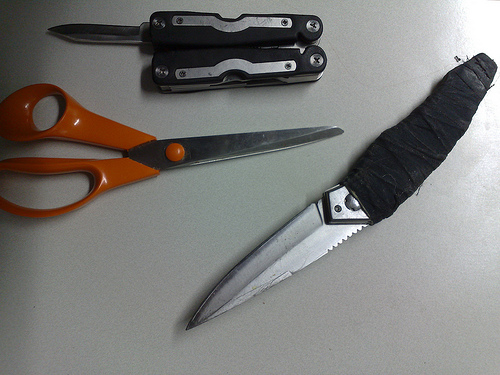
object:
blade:
[179, 198, 326, 346]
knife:
[189, 46, 480, 346]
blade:
[48, 17, 154, 55]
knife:
[38, 12, 321, 40]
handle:
[4, 83, 157, 225]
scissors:
[4, 83, 348, 219]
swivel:
[160, 142, 186, 171]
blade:
[161, 115, 345, 171]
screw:
[309, 47, 328, 77]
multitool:
[144, 7, 328, 101]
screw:
[304, 10, 324, 39]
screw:
[147, 7, 174, 34]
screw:
[150, 60, 171, 85]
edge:
[261, 235, 350, 303]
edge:
[257, 140, 333, 159]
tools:
[114, 8, 380, 298]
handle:
[372, 51, 479, 217]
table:
[337, 15, 384, 95]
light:
[462, 5, 494, 142]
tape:
[432, 55, 469, 163]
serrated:
[323, 206, 379, 257]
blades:
[196, 124, 345, 159]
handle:
[167, 8, 257, 97]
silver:
[208, 12, 250, 39]